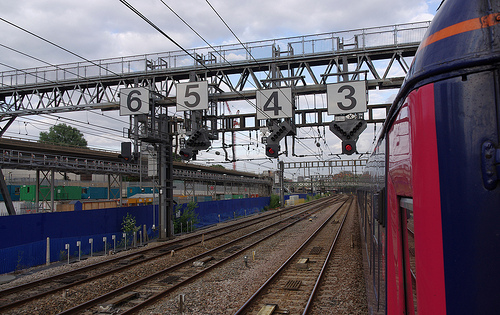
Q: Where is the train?
A: On the tracks.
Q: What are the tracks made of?
A: Metal.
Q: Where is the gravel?
A: Next to the tracks.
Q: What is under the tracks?
A: Gravel.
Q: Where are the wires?
A: In air over the tracks.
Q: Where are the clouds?
A: In the sky.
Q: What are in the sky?
A: Clouds.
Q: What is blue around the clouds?
A: The sky.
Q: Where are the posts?
A: At the edge of the tracks.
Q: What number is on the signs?
A: 6543.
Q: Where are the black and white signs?
A: Over the tracks.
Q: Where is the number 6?
A: On the sign.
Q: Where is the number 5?
A: On the sign.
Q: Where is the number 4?
A: On the sign.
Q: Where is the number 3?
A: On the sign.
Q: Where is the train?
A: On the tracks.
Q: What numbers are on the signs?
A: 6543.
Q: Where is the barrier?
A: On the tracks.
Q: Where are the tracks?
A: On the ground.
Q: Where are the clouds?
A: In the sky.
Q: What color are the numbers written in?
A: Black.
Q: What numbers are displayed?
A: 6, 5, 4 and 3.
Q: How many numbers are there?
A: Four.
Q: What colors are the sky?
A: Gray and blue.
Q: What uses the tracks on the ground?
A: Trains.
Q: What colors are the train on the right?
A: Red and blue.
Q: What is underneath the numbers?
A: Lights.